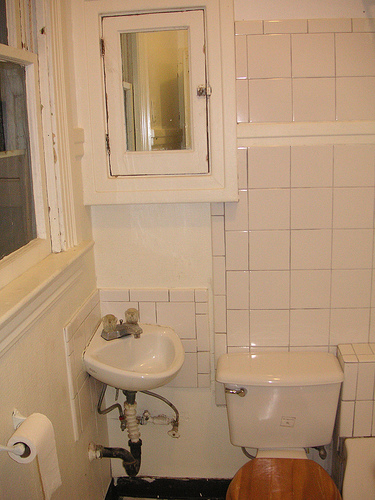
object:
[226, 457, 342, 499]
toilet lid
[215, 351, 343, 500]
toilet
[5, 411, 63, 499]
toilet paper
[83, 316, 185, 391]
corner sink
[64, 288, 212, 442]
walls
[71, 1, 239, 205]
medicine cabinet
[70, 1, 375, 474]
wall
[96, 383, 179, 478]
plumbing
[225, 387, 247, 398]
flush handle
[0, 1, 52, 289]
window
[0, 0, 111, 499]
wall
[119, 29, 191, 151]
mirror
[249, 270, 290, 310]
tile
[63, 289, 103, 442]
tile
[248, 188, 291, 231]
tile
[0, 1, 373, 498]
bathroom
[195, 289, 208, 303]
tiles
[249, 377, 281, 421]
reflection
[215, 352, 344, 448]
tank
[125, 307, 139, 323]
knob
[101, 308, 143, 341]
faucet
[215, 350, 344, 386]
lid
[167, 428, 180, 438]
valve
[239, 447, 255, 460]
pipe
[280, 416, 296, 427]
sticker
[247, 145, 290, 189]
tile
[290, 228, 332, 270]
tile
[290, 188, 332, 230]
tile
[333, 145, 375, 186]
tile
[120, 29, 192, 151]
reflection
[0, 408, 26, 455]
toilet paper holder